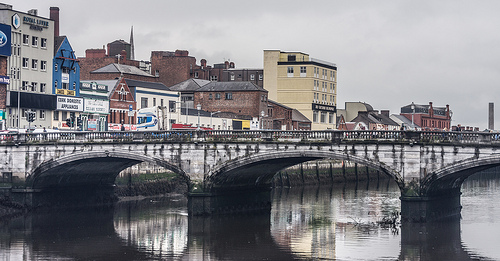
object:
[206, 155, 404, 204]
archway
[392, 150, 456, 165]
ground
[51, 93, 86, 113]
sign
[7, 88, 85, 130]
building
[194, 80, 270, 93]
pointed roof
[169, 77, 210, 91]
pointed roof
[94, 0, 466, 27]
cloud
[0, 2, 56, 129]
building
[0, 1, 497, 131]
sky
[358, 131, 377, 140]
cars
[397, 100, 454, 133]
building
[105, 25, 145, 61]
building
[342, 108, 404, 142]
house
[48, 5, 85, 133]
building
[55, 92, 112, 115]
two signs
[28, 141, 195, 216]
arch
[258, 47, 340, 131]
yellow building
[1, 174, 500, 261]
river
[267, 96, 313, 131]
building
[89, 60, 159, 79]
roof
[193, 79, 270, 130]
building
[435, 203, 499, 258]
water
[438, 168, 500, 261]
reflection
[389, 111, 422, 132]
house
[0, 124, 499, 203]
bridge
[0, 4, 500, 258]
city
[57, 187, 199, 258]
reflection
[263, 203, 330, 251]
water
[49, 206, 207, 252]
water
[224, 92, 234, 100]
windows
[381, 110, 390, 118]
chimney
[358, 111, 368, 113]
chimney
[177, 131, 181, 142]
poles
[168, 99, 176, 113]
windows